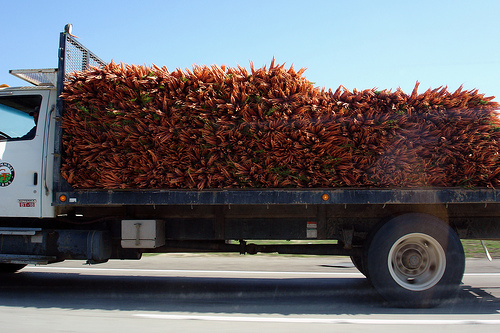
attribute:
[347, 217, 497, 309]
tire — black, rear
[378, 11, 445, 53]
sky — clear, blue, cloudless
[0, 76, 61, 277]
front — white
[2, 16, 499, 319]
truck — full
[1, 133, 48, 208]
cab — white 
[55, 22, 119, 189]
back — metal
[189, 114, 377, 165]
plants — piled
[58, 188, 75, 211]
light — round, orange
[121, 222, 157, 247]
white box — is white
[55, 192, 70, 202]
light — orange